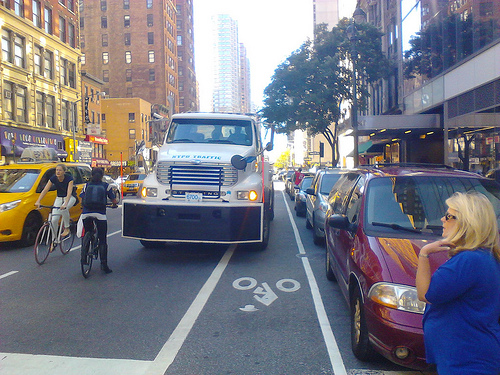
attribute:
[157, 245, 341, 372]
lines — solid, painted, white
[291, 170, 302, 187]
shirt — red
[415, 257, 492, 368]
shirt — blue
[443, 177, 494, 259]
woman's hair — blonde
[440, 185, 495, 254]
hair — blonde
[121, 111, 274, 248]
truck — large, white, big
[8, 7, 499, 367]
street — crowded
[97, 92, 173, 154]
building — yellow, short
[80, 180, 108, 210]
backpack — blue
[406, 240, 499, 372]
shirt — blue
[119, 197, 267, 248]
bumper — big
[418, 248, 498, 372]
shirt — blue